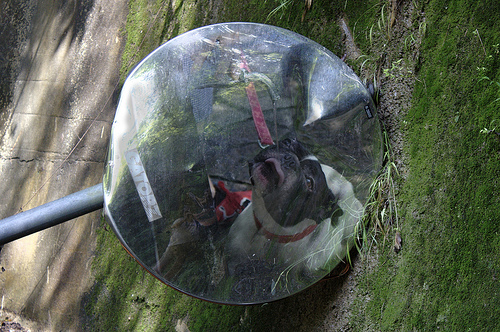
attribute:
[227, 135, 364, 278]
dog — looking, reflected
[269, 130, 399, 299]
grass — green, gron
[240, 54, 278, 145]
stripe — handle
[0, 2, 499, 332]
ground — real, realy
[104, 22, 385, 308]
glass — real